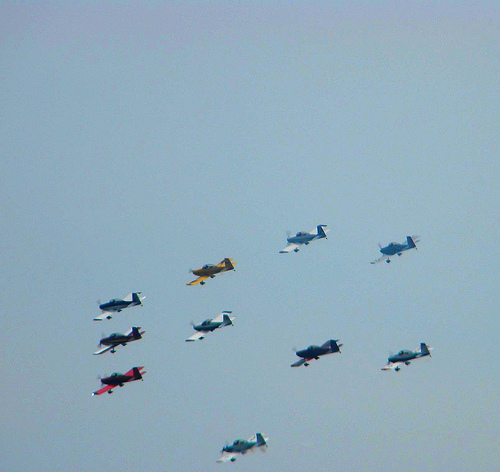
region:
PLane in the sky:
[76, 280, 156, 314]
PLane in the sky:
[92, 330, 156, 364]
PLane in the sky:
[83, 364, 186, 411]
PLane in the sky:
[188, 412, 267, 464]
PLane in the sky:
[181, 310, 238, 345]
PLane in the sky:
[167, 245, 246, 297]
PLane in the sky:
[281, 216, 344, 258]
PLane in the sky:
[288, 328, 338, 383]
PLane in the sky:
[368, 336, 466, 376]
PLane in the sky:
[364, 211, 416, 288]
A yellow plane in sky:
[175, 246, 238, 292]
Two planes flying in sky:
[182, 251, 247, 351]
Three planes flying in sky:
[81, 284, 156, 409]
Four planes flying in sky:
[281, 222, 443, 382]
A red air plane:
[83, 362, 156, 399]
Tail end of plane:
[124, 364, 146, 384]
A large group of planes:
[75, 204, 443, 456]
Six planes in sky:
[176, 217, 466, 394]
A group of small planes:
[52, 222, 454, 464]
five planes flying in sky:
[77, 235, 259, 412]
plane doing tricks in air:
[70, 285, 153, 320]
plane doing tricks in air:
[70, 327, 147, 352]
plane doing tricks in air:
[82, 361, 156, 400]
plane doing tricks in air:
[177, 253, 263, 318]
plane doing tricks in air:
[176, 305, 243, 352]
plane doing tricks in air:
[202, 413, 283, 470]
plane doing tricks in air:
[289, 331, 359, 401]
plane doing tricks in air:
[364, 335, 440, 386]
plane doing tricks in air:
[275, 219, 337, 265]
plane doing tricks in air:
[367, 217, 420, 278]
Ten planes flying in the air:
[77, 222, 466, 461]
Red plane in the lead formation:
[86, 362, 147, 406]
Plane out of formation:
[211, 430, 297, 462]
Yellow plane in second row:
[183, 256, 240, 286]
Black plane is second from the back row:
[293, 334, 343, 369]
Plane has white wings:
[187, 311, 239, 344]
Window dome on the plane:
[107, 370, 123, 379]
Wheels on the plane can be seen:
[382, 249, 404, 265]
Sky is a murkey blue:
[10, 214, 145, 280]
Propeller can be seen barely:
[93, 293, 102, 309]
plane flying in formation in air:
[85, 285, 156, 322]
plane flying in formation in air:
[87, 323, 151, 357]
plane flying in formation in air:
[67, 361, 168, 409]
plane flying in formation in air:
[192, 409, 280, 466]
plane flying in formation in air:
[187, 309, 238, 350]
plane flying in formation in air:
[272, 319, 350, 380]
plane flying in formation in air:
[371, 323, 439, 390]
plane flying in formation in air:
[284, 218, 339, 258]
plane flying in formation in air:
[358, 219, 435, 281]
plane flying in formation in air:
[177, 245, 238, 283]